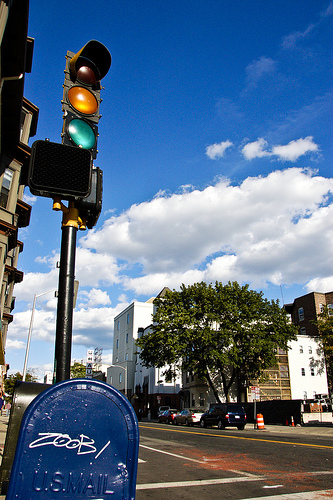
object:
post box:
[5, 376, 141, 500]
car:
[199, 403, 247, 431]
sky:
[3, 0, 331, 386]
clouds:
[182, 223, 196, 244]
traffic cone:
[256, 412, 265, 429]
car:
[173, 407, 205, 427]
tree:
[134, 278, 301, 403]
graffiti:
[27, 430, 112, 461]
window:
[0, 165, 16, 212]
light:
[59, 36, 114, 162]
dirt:
[165, 444, 333, 500]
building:
[105, 298, 153, 400]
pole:
[55, 207, 79, 389]